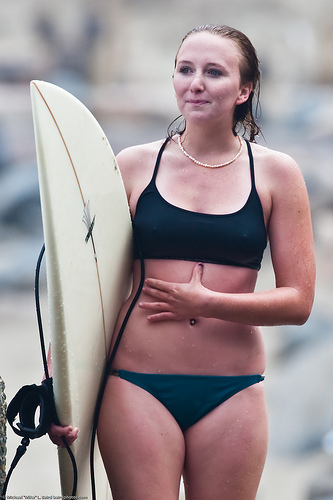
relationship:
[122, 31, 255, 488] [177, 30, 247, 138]
woman has head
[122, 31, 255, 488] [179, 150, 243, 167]
woman has necklace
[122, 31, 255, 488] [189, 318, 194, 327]
woman has bellybutton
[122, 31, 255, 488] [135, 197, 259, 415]
woman wearing bathing suit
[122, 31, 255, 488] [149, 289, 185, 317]
woman has hand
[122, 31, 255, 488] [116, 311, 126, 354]
woman has leash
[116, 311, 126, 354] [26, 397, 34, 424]
leash has velcro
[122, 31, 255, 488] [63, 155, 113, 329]
woman holding surfboard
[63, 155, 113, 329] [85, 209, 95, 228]
surfboard has logo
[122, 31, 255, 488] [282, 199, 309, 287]
woman has arm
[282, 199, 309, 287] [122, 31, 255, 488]
arm of woman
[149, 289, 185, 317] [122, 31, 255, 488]
hand of woman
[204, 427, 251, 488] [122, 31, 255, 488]
leg of woman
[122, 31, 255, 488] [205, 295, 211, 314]
woman has wrist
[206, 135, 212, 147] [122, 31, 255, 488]
neck of woman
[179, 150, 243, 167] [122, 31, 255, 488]
necklace of woman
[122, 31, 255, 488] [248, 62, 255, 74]
woman has hair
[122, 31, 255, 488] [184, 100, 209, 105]
woman has lips